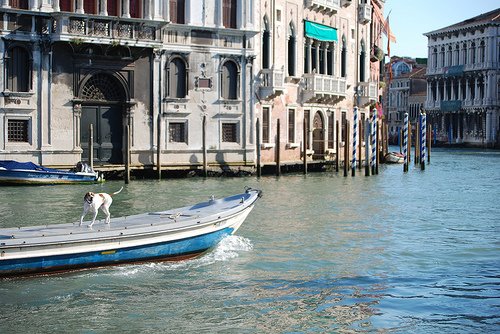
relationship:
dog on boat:
[77, 180, 128, 227] [0, 185, 265, 283]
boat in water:
[0, 185, 265, 283] [3, 173, 499, 333]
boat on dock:
[2, 157, 106, 187] [3, 159, 319, 176]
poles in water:
[251, 113, 351, 177] [3, 173, 499, 333]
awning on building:
[303, 21, 339, 43] [0, 0, 386, 180]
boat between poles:
[2, 157, 106, 187] [85, 121, 137, 184]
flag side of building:
[380, 9, 402, 46] [370, 4, 392, 163]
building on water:
[0, 0, 386, 180] [3, 173, 499, 333]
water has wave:
[3, 173, 499, 333] [212, 232, 257, 259]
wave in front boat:
[212, 232, 257, 259] [0, 185, 265, 283]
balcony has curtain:
[297, 13, 351, 107] [303, 21, 339, 43]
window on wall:
[217, 56, 246, 101] [157, 24, 260, 162]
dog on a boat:
[77, 180, 128, 227] [0, 185, 265, 283]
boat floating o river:
[0, 185, 265, 283] [3, 173, 499, 333]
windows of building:
[12, 1, 250, 30] [384, 8, 499, 149]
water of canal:
[3, 173, 499, 333] [2, 143, 498, 332]